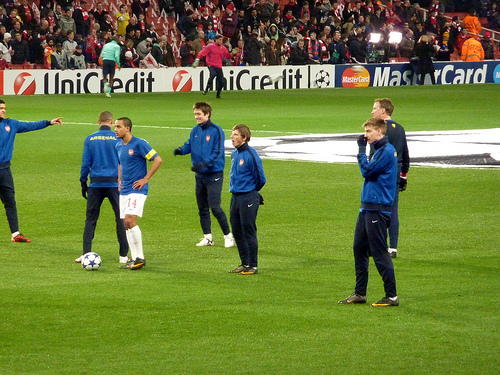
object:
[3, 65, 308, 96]
board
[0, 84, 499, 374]
lawn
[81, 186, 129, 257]
pants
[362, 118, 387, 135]
brown hair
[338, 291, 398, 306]
shoes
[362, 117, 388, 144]
head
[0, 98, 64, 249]
player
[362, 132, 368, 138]
nose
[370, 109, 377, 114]
nose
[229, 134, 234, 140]
nose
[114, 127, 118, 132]
nose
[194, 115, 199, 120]
nose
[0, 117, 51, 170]
blue jacket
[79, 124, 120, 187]
blue jacket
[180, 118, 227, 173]
blue jacket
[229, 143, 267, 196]
blue jacket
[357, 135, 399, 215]
blue jacket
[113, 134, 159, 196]
shirt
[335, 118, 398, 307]
blueshirt person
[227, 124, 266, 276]
blueshirt person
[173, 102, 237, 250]
blueshirt person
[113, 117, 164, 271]
blueshirt person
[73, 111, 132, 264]
blueshirt person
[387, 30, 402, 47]
light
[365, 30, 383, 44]
light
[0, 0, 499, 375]
field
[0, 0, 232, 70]
people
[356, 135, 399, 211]
blue jacket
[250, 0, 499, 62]
crowd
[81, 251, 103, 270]
ball part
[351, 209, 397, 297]
pants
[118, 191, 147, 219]
shorts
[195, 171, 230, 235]
pants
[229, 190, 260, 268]
pants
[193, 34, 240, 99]
people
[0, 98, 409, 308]
teammate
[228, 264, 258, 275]
shoes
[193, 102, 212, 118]
hair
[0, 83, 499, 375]
soccer game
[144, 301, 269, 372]
part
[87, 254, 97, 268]
part